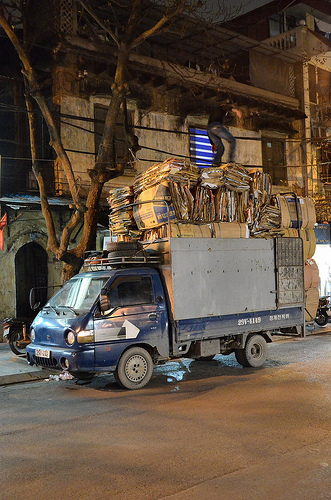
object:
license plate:
[36, 348, 50, 358]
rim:
[116, 344, 154, 390]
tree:
[2, 5, 184, 313]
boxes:
[103, 175, 136, 231]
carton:
[213, 218, 250, 239]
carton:
[167, 222, 214, 237]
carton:
[223, 160, 249, 190]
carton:
[277, 193, 316, 229]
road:
[0, 384, 331, 500]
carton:
[261, 204, 279, 231]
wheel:
[234, 333, 268, 367]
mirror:
[99, 293, 111, 311]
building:
[0, 1, 331, 218]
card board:
[133, 182, 175, 229]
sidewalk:
[1, 356, 25, 379]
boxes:
[199, 162, 252, 191]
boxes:
[131, 157, 198, 190]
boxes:
[251, 167, 272, 205]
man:
[206, 97, 243, 168]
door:
[95, 273, 160, 368]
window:
[189, 123, 218, 167]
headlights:
[63, 326, 76, 348]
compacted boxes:
[216, 187, 235, 223]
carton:
[191, 187, 215, 222]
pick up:
[22, 229, 308, 391]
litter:
[49, 369, 74, 381]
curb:
[0, 367, 45, 385]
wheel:
[115, 345, 152, 390]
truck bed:
[172, 232, 303, 343]